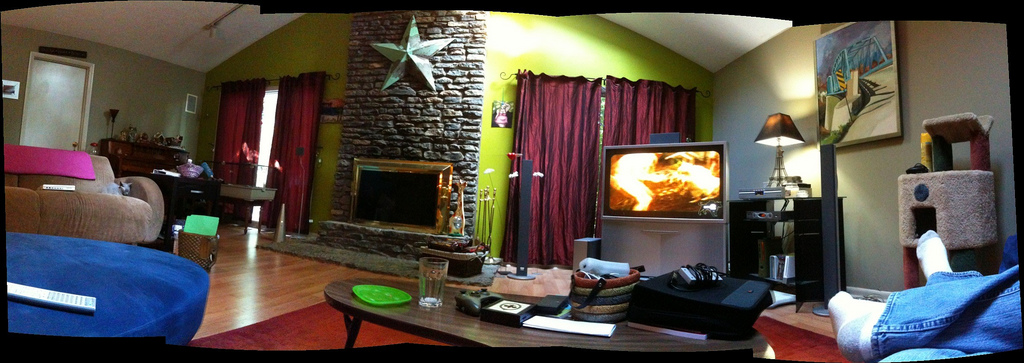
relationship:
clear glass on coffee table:
[418, 257, 450, 307] [323, 277, 766, 359]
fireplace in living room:
[343, 147, 469, 236] [0, 0, 1024, 363]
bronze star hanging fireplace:
[370, 14, 455, 92] [348, 158, 453, 235]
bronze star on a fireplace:
[370, 14, 455, 92] [315, 10, 486, 261]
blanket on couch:
[2, 136, 113, 201] [8, 139, 181, 269]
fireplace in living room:
[315, 10, 486, 261] [30, 18, 1000, 314]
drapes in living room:
[259, 85, 311, 241] [209, 80, 856, 359]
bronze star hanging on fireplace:
[370, 14, 455, 92] [339, 28, 480, 251]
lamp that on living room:
[754, 96, 811, 202] [222, 41, 1018, 323]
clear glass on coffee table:
[418, 257, 450, 307] [322, 258, 636, 358]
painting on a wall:
[801, 28, 916, 152] [603, 41, 1021, 351]